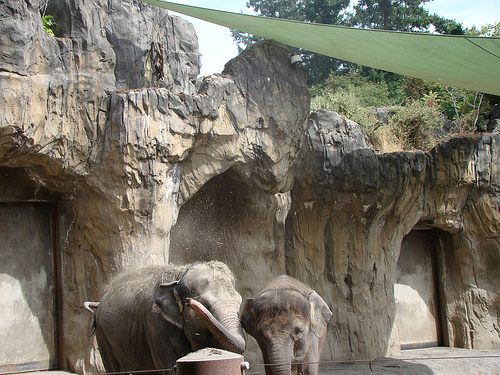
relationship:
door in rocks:
[396, 240, 444, 348] [142, 105, 183, 138]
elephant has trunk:
[93, 279, 253, 360] [189, 297, 240, 344]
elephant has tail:
[93, 279, 253, 360] [83, 288, 108, 336]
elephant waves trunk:
[93, 279, 253, 360] [189, 297, 240, 344]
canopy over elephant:
[368, 41, 400, 66] [240, 274, 334, 375]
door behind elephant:
[396, 240, 444, 348] [240, 274, 334, 375]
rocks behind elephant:
[142, 105, 183, 138] [240, 274, 334, 375]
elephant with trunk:
[240, 274, 334, 375] [189, 297, 240, 344]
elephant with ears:
[256, 266, 332, 375] [303, 291, 338, 338]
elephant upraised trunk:
[93, 279, 253, 360] [189, 297, 240, 344]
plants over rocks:
[353, 109, 406, 131] [142, 105, 183, 138]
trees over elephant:
[366, 8, 391, 33] [240, 274, 334, 375]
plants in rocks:
[353, 109, 406, 131] [142, 105, 183, 138]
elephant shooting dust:
[240, 274, 334, 375] [165, 275, 194, 304]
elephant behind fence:
[240, 274, 334, 375] [354, 350, 475, 375]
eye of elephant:
[290, 318, 326, 343] [93, 279, 253, 360]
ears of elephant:
[303, 291, 338, 338] [93, 279, 253, 360]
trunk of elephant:
[189, 297, 240, 344] [93, 279, 253, 360]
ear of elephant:
[151, 278, 186, 322] [93, 279, 253, 360]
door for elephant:
[396, 240, 444, 348] [240, 274, 334, 375]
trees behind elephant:
[366, 8, 391, 33] [240, 274, 334, 375]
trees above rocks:
[366, 8, 391, 33] [142, 105, 183, 138]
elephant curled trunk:
[93, 279, 253, 360] [189, 297, 240, 344]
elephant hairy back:
[240, 274, 334, 375] [96, 271, 220, 301]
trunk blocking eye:
[189, 297, 240, 344] [290, 318, 326, 343]